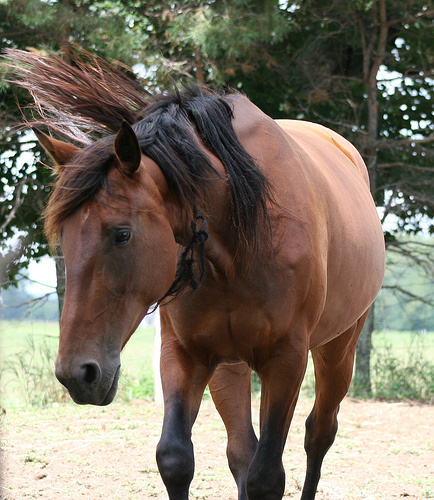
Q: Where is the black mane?
A: On horse.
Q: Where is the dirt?
A: Below the horse.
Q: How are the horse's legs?
A: In motion.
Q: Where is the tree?
A: Behind horse.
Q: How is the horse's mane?
A: Blowing.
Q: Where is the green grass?
A: Behind the horse.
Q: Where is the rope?
A: Around the horse neck.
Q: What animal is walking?
A: A horse.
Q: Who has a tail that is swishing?
A: The horse.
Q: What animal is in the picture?
A: A horse.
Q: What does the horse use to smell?
A: A nose.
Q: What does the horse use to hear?
A: Ears.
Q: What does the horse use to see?
A: Eyes.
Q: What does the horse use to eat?
A: A mouth.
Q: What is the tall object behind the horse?
A: A tree.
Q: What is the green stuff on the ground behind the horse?
A: Grass.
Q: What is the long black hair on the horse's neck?
A: Mane.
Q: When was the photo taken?
A: Daytime.